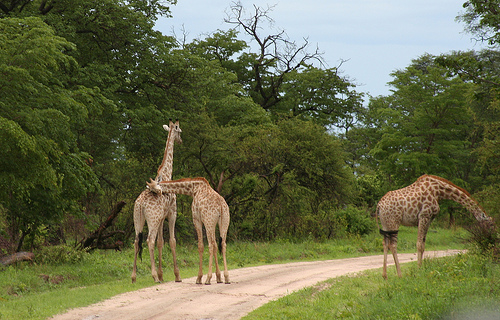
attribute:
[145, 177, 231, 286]
giraffe — here, scratching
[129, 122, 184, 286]
giraffe — adult, here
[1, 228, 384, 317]
grass — green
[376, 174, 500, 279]
giraffe — grazing, eating, here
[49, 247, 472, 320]
road — dirty, small, sandy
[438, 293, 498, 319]
hole — small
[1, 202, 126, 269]
tree — green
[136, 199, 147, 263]
tail — long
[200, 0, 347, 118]
tree — bare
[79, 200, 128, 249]
log — bare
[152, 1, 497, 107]
sky — blue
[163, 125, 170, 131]
ear — white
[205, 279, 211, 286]
hoof — cloven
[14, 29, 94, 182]
leaves — green